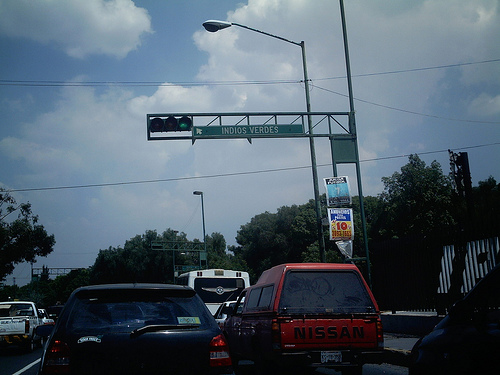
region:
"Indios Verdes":
[186, 119, 323, 144]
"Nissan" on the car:
[285, 316, 382, 353]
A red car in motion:
[233, 259, 415, 369]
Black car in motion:
[36, 266, 246, 373]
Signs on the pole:
[314, 163, 384, 263]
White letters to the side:
[423, 220, 499, 308]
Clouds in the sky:
[5, 3, 499, 225]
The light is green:
[135, 108, 196, 143]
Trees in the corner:
[3, 181, 68, 295]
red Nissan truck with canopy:
[225, 262, 384, 367]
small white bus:
[176, 268, 250, 318]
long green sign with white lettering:
[192, 123, 304, 136]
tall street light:
[194, 188, 205, 239]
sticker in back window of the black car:
[177, 315, 199, 325]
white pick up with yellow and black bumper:
[1, 300, 43, 348]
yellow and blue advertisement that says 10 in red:
[328, 207, 354, 239]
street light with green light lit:
[148, 115, 191, 131]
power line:
[0, 138, 499, 192]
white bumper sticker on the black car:
[77, 335, 100, 345]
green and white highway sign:
[133, 110, 340, 143]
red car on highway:
[238, 249, 380, 358]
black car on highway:
[52, 272, 221, 367]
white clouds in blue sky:
[9, 7, 70, 62]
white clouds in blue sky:
[16, 71, 68, 105]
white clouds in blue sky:
[36, 95, 116, 160]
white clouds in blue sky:
[73, 139, 107, 194]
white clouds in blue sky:
[90, 25, 174, 82]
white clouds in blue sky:
[370, 26, 439, 73]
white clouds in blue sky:
[371, 69, 455, 140]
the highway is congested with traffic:
[6, 174, 492, 369]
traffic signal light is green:
[134, 98, 369, 150]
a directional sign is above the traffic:
[188, 122, 304, 142]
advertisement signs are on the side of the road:
[318, 170, 360, 270]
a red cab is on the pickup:
[221, 262, 380, 369]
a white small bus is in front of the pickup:
[171, 262, 251, 331]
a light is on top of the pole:
[184, 185, 221, 271]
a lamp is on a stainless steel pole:
[195, 15, 329, 362]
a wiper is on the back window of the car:
[62, 287, 212, 342]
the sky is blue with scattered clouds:
[13, 9, 494, 223]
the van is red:
[228, 257, 401, 364]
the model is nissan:
[286, 318, 378, 355]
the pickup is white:
[1, 298, 43, 348]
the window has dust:
[271, 275, 373, 320]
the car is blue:
[42, 279, 229, 368]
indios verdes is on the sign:
[213, 119, 293, 147]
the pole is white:
[436, 239, 493, 298]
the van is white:
[177, 265, 249, 301]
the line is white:
[14, 352, 40, 374]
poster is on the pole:
[323, 204, 359, 246]